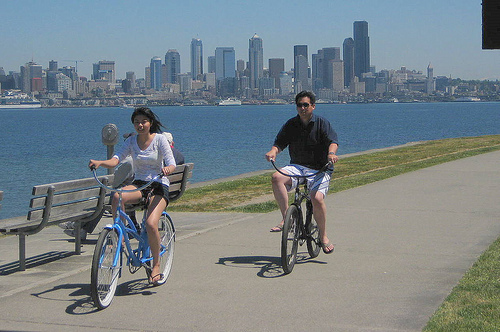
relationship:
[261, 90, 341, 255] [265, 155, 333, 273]
man riding bicycle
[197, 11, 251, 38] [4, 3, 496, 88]
clouds in sky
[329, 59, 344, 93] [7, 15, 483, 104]
building in city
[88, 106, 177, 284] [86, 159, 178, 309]
woman riding bicycle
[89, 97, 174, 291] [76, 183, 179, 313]
woman riding bicycle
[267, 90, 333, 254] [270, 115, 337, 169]
man wearing top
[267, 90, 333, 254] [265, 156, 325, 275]
man riding bicycle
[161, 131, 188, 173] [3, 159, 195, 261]
person sitting on bench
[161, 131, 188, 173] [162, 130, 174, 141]
person has hair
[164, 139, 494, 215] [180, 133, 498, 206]
patch has grass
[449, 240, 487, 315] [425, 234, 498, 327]
patch has grass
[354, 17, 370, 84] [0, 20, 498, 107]
building in city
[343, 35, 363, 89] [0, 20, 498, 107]
building in city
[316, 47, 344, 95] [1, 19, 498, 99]
building in city